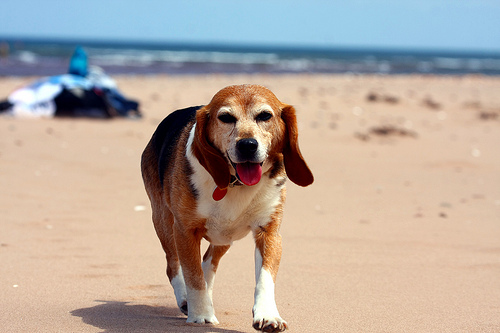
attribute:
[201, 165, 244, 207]
tag — red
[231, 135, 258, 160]
nose — black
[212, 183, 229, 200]
tag — red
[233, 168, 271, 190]
tongue — red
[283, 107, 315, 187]
ear — floppy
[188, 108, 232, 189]
ear — floppy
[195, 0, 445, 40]
sky — blue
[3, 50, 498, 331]
sandy beach — tan colored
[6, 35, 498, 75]
ocean — blue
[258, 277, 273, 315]
fur — white